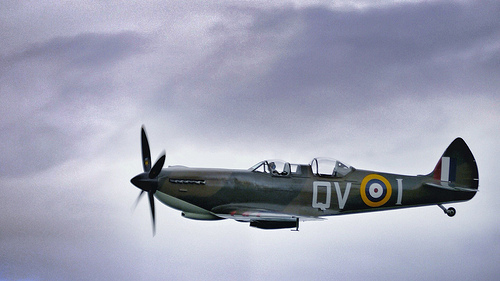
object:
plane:
[127, 123, 479, 236]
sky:
[0, 0, 497, 280]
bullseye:
[358, 173, 392, 208]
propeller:
[128, 125, 165, 238]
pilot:
[269, 162, 281, 176]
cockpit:
[249, 159, 303, 178]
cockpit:
[309, 157, 355, 180]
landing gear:
[438, 204, 457, 217]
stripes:
[441, 157, 451, 182]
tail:
[425, 137, 480, 205]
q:
[312, 181, 332, 211]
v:
[333, 181, 351, 209]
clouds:
[190, 54, 319, 121]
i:
[395, 177, 403, 205]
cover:
[311, 157, 352, 178]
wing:
[212, 205, 329, 223]